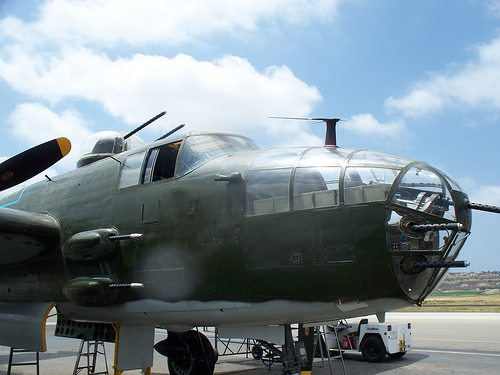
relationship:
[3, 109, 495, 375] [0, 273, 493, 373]
airplane at airport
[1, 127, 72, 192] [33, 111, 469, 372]
propeller attached to bomber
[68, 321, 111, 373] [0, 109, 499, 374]
ladder leading to bomber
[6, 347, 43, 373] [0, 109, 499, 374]
ladder leading to bomber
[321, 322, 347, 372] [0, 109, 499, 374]
ladder leading to bomber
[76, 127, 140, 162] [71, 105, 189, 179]
turret belongs to bomber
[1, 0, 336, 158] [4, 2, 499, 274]
cloud in sky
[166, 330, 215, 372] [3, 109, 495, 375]
wheel attached to airplane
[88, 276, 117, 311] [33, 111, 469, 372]
engine attached to bomber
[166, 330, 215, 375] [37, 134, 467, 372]
wheel attached to bomber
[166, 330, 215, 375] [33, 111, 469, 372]
wheel attached to bomber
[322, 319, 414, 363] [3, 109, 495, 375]
vehicle in front of airplane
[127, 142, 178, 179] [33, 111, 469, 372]
window on side of bomber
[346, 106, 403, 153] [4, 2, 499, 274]
cloud in sky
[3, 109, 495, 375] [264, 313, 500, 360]
airplane on land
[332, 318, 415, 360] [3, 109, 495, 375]
vehicle next to airplane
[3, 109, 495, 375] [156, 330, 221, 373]
airplane has wheel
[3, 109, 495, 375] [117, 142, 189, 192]
airplane has windows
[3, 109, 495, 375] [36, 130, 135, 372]
airplane has accents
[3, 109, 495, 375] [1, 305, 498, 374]
airplane on ground